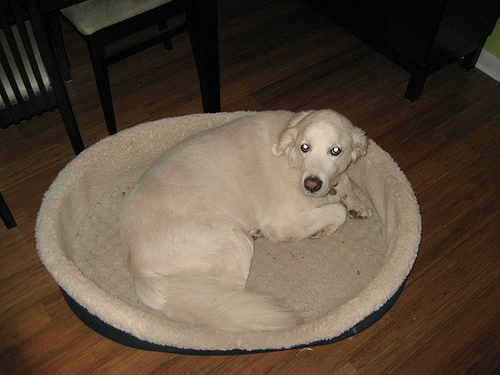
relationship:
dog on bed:
[113, 118, 363, 317] [30, 115, 421, 349]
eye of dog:
[299, 143, 312, 153] [113, 118, 363, 317]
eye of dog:
[330, 146, 345, 158] [113, 118, 363, 317]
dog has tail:
[113, 118, 363, 317] [161, 289, 302, 327]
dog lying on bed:
[113, 118, 363, 317] [30, 115, 421, 349]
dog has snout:
[113, 118, 363, 317] [296, 168, 331, 197]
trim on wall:
[475, 50, 499, 77] [486, 26, 499, 55]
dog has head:
[113, 118, 363, 317] [276, 104, 367, 197]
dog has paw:
[113, 118, 363, 317] [339, 196, 371, 221]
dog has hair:
[113, 118, 363, 317] [145, 233, 164, 247]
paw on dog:
[313, 228, 333, 241] [113, 118, 363, 317]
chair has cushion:
[49, 5, 239, 105] [69, 2, 169, 29]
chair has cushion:
[3, 4, 80, 154] [2, 20, 49, 92]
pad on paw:
[349, 208, 358, 216] [339, 196, 371, 221]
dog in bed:
[113, 118, 363, 317] [30, 115, 421, 349]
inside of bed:
[62, 194, 113, 254] [30, 115, 421, 349]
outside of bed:
[63, 299, 119, 335] [30, 115, 421, 349]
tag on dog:
[330, 187, 338, 195] [113, 118, 363, 317]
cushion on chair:
[69, 2, 169, 29] [49, 5, 239, 105]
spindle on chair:
[12, 8, 24, 31] [49, 5, 239, 105]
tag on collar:
[330, 187, 338, 195] [334, 183, 340, 187]